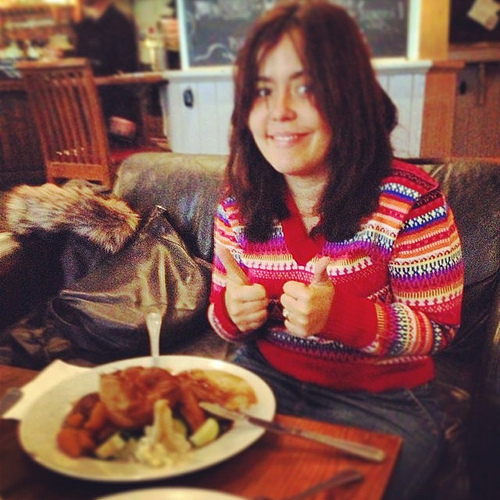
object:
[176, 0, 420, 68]
chalk board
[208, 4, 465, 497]
girl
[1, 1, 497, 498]
restaurant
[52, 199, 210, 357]
purse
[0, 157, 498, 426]
couch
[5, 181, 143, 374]
jacket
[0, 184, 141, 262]
fur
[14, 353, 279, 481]
dinner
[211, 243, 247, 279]
thumb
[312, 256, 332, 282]
thumb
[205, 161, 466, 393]
sweater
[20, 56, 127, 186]
chair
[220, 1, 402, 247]
hair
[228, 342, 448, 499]
jeans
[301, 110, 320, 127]
skin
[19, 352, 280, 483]
plate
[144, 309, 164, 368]
spoon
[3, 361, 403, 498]
table